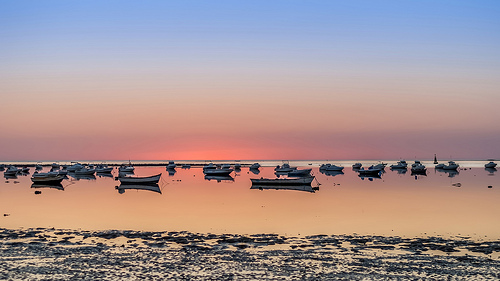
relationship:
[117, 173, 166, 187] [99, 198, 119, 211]
boats are on beach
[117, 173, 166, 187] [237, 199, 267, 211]
boats are in water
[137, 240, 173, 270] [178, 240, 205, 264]
ground has tracks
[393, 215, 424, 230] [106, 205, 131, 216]
reflection on sand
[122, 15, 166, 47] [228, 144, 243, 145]
sky of evening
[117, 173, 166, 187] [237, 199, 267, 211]
boats in water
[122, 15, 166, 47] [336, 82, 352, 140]
sky has colors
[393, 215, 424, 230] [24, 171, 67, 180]
reflection of a boat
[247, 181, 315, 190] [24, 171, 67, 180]
bottom of a boat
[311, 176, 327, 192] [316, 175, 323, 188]
part of a string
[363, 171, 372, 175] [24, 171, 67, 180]
edge of a boat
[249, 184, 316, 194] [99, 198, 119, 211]
shadow on beach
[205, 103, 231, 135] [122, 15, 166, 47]
rays are in sky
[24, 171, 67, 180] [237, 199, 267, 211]
boat in water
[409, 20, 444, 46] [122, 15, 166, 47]
no clouds are in sky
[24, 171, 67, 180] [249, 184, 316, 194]
boat leaves a shadow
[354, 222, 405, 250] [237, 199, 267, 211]
land near water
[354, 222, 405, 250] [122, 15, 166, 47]
land under sky